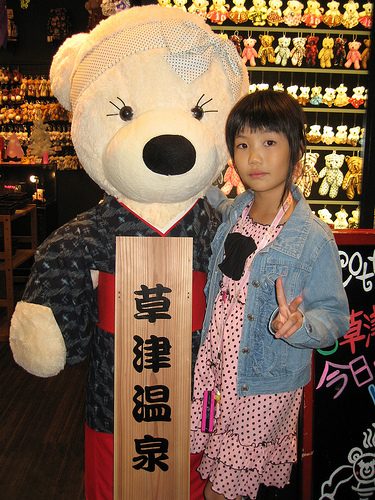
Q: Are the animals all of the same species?
A: Yes, all the animals are bears.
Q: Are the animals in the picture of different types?
A: No, all the animals are bears.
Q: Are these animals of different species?
A: No, all the animals are bears.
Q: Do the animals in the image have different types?
A: No, all the animals are bears.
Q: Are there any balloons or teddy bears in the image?
A: Yes, there is a teddy bear.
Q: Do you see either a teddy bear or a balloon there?
A: Yes, there is a teddy bear.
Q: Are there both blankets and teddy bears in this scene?
A: No, there is a teddy bear but no blankets.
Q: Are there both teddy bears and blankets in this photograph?
A: No, there is a teddy bear but no blankets.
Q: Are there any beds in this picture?
A: No, there are no beds.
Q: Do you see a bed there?
A: No, there are no beds.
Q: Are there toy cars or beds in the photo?
A: No, there are no beds or toy cars.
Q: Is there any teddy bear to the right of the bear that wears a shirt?
A: Yes, there is a teddy bear to the right of the bear.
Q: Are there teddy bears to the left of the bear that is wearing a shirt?
A: No, the teddy bear is to the right of the bear.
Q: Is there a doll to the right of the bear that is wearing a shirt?
A: No, there is a teddy bear to the right of the bear.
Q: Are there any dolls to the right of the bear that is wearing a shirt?
A: No, there is a teddy bear to the right of the bear.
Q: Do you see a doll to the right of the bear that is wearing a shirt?
A: No, there is a teddy bear to the right of the bear.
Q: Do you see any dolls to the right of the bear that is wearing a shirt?
A: No, there is a teddy bear to the right of the bear.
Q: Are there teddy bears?
A: Yes, there is a teddy bear.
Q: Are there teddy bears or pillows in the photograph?
A: Yes, there is a teddy bear.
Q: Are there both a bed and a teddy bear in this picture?
A: No, there is a teddy bear but no beds.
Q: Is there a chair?
A: No, there are no chairs.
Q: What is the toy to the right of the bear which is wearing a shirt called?
A: The toy is a teddy bear.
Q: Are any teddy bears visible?
A: Yes, there is a teddy bear.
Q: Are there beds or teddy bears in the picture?
A: Yes, there is a teddy bear.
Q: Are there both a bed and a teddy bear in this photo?
A: No, there is a teddy bear but no beds.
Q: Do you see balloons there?
A: No, there are no balloons.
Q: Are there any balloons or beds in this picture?
A: No, there are no balloons or beds.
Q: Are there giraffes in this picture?
A: No, there are no giraffes.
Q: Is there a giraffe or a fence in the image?
A: No, there are no giraffes or fences.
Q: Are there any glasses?
A: No, there are no glasses.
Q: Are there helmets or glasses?
A: No, there are no glasses or helmets.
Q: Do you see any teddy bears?
A: Yes, there is a teddy bear.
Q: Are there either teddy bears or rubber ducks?
A: Yes, there is a teddy bear.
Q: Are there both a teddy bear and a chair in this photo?
A: No, there is a teddy bear but no chairs.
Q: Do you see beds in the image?
A: No, there are no beds.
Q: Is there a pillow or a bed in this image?
A: No, there are no beds or pillows.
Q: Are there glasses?
A: No, there are no glasses.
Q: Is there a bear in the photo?
A: Yes, there is a bear.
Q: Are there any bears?
A: Yes, there is a bear.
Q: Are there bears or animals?
A: Yes, there is a bear.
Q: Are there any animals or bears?
A: Yes, there is a bear.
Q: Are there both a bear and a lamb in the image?
A: No, there is a bear but no lambs.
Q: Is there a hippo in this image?
A: No, there are no hippos.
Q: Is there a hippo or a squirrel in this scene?
A: No, there are no hippos or squirrels.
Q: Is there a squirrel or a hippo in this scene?
A: No, there are no hippos or squirrels.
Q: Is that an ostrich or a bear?
A: That is a bear.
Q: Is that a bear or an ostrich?
A: That is a bear.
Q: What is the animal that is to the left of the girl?
A: The animal is a bear.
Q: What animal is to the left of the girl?
A: The animal is a bear.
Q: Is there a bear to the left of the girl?
A: Yes, there is a bear to the left of the girl.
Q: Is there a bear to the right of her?
A: No, the bear is to the left of the girl.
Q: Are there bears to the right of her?
A: No, the bear is to the left of the girl.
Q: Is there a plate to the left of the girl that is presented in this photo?
A: No, there is a bear to the left of the girl.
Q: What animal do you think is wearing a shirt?
A: The bear is wearing a shirt.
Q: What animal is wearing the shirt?
A: The bear is wearing a shirt.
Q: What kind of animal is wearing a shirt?
A: The animal is a bear.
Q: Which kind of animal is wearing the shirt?
A: The animal is a bear.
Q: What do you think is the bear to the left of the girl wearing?
A: The bear is wearing a shirt.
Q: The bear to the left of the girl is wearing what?
A: The bear is wearing a shirt.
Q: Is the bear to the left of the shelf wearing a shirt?
A: Yes, the bear is wearing a shirt.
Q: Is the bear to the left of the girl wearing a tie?
A: No, the bear is wearing a shirt.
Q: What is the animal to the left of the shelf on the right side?
A: The animal is a bear.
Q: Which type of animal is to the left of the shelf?
A: The animal is a bear.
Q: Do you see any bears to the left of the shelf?
A: Yes, there is a bear to the left of the shelf.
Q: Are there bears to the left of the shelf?
A: Yes, there is a bear to the left of the shelf.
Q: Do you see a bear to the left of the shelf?
A: Yes, there is a bear to the left of the shelf.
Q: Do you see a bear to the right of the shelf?
A: No, the bear is to the left of the shelf.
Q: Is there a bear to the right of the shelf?
A: No, the bear is to the left of the shelf.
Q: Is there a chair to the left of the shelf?
A: No, there is a bear to the left of the shelf.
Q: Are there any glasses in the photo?
A: No, there are no glasses.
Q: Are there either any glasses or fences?
A: No, there are no glasses or fences.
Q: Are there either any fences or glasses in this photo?
A: No, there are no glasses or fences.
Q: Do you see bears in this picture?
A: Yes, there is a bear.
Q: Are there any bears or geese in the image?
A: Yes, there is a bear.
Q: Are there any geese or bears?
A: Yes, there is a bear.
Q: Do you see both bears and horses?
A: No, there is a bear but no horses.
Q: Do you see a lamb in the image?
A: No, there are no lambs.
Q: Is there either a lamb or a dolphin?
A: No, there are no lambs or dolphins.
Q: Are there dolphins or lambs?
A: No, there are no lambs or dolphins.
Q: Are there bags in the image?
A: No, there are no bags.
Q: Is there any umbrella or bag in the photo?
A: No, there are no bags or umbrellas.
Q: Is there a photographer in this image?
A: No, there are no photographers.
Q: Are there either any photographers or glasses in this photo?
A: No, there are no photographers or glasses.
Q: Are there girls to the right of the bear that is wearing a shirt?
A: Yes, there is a girl to the right of the bear.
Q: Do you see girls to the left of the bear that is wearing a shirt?
A: No, the girl is to the right of the bear.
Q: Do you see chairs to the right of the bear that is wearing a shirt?
A: No, there is a girl to the right of the bear.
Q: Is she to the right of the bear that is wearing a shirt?
A: Yes, the girl is to the right of the bear.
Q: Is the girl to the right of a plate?
A: No, the girl is to the right of the bear.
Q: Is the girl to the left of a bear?
A: No, the girl is to the right of a bear.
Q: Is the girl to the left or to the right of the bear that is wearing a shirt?
A: The girl is to the right of the bear.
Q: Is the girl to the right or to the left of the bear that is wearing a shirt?
A: The girl is to the right of the bear.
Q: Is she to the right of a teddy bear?
A: No, the girl is to the left of a teddy bear.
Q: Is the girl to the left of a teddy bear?
A: Yes, the girl is to the left of a teddy bear.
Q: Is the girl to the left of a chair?
A: No, the girl is to the left of a teddy bear.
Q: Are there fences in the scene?
A: No, there are no fences.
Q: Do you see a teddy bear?
A: Yes, there is a teddy bear.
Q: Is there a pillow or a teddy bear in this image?
A: Yes, there is a teddy bear.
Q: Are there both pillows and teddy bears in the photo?
A: No, there is a teddy bear but no pillows.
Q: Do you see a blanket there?
A: No, there are no blankets.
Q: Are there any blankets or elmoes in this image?
A: No, there are no blankets or elmoes.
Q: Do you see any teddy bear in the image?
A: Yes, there is a teddy bear.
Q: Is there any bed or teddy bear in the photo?
A: Yes, there is a teddy bear.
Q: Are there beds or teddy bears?
A: Yes, there is a teddy bear.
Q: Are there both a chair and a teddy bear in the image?
A: No, there is a teddy bear but no chairs.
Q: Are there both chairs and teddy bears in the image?
A: No, there is a teddy bear but no chairs.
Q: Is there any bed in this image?
A: No, there are no beds.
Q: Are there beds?
A: No, there are no beds.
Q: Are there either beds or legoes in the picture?
A: No, there are no beds or legoes.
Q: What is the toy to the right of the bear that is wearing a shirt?
A: The toy is a teddy bear.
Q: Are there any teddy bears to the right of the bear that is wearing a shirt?
A: Yes, there is a teddy bear to the right of the bear.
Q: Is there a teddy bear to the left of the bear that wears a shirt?
A: No, the teddy bear is to the right of the bear.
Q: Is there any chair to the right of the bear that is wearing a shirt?
A: No, there is a teddy bear to the right of the bear.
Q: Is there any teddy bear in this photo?
A: Yes, there is a teddy bear.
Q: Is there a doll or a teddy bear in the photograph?
A: Yes, there is a teddy bear.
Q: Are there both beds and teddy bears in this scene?
A: No, there is a teddy bear but no beds.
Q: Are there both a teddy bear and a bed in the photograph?
A: No, there is a teddy bear but no beds.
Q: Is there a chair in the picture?
A: No, there are no chairs.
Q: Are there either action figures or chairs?
A: No, there are no chairs or action figures.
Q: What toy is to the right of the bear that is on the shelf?
A: The toy is a teddy bear.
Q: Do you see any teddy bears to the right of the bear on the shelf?
A: Yes, there is a teddy bear to the right of the bear.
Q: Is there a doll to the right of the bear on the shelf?
A: No, there is a teddy bear to the right of the bear.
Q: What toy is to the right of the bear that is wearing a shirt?
A: The toy is a teddy bear.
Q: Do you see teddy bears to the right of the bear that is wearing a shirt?
A: Yes, there is a teddy bear to the right of the bear.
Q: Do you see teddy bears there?
A: Yes, there is a teddy bear.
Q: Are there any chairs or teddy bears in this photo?
A: Yes, there is a teddy bear.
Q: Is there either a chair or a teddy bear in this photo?
A: Yes, there is a teddy bear.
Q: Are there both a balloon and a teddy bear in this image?
A: No, there is a teddy bear but no balloons.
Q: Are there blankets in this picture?
A: No, there are no blankets.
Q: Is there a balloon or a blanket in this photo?
A: No, there are no blankets or balloons.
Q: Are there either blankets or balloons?
A: No, there are no blankets or balloons.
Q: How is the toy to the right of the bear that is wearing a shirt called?
A: The toy is a teddy bear.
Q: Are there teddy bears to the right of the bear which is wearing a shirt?
A: Yes, there is a teddy bear to the right of the bear.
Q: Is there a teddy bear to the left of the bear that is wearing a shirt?
A: No, the teddy bear is to the right of the bear.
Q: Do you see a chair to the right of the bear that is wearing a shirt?
A: No, there is a teddy bear to the right of the bear.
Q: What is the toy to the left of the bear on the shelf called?
A: The toy is a teddy bear.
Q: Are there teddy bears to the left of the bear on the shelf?
A: Yes, there is a teddy bear to the left of the bear.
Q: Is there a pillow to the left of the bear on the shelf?
A: No, there is a teddy bear to the left of the bear.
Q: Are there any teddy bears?
A: Yes, there is a teddy bear.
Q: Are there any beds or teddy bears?
A: Yes, there is a teddy bear.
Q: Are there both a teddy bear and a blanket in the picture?
A: No, there is a teddy bear but no blankets.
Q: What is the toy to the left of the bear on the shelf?
A: The toy is a teddy bear.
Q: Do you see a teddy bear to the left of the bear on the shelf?
A: Yes, there is a teddy bear to the left of the bear.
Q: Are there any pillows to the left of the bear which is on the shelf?
A: No, there is a teddy bear to the left of the bear.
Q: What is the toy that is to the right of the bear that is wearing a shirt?
A: The toy is a teddy bear.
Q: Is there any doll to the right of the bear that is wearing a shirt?
A: No, there is a teddy bear to the right of the bear.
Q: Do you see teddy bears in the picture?
A: Yes, there is a teddy bear.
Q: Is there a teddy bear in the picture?
A: Yes, there is a teddy bear.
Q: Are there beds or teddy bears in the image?
A: Yes, there is a teddy bear.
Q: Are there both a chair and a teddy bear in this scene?
A: No, there is a teddy bear but no chairs.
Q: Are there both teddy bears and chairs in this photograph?
A: No, there is a teddy bear but no chairs.